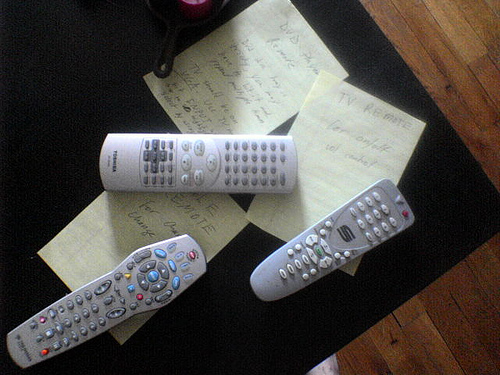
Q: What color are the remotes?
A: Gray.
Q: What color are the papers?
A: Yellow.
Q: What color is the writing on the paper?
A: Brown.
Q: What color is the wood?
A: Brown.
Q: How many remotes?
A: Three.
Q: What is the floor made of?
A: Wood.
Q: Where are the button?
A: On remote.